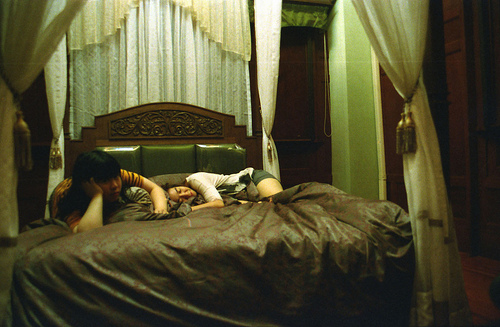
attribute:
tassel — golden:
[394, 108, 418, 157]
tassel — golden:
[11, 106, 35, 174]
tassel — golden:
[46, 135, 64, 171]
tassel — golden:
[264, 138, 277, 165]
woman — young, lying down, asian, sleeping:
[151, 164, 286, 201]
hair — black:
[160, 180, 187, 190]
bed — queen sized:
[6, 99, 427, 327]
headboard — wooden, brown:
[55, 102, 268, 187]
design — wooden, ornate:
[105, 109, 228, 142]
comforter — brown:
[9, 172, 415, 326]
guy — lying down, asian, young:
[48, 147, 174, 235]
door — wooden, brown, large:
[241, 21, 340, 195]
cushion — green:
[194, 140, 246, 176]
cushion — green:
[141, 142, 199, 177]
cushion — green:
[93, 144, 142, 175]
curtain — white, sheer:
[64, 0, 254, 142]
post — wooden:
[244, 0, 264, 137]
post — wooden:
[60, 22, 76, 144]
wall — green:
[325, 3, 385, 211]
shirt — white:
[180, 162, 256, 205]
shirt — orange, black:
[48, 169, 147, 231]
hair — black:
[55, 147, 124, 216]